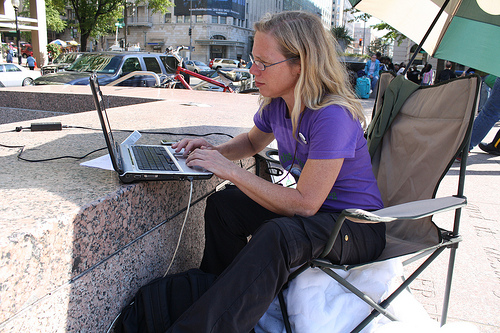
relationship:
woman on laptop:
[250, 21, 374, 267] [88, 73, 185, 194]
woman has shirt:
[250, 21, 374, 267] [278, 104, 382, 217]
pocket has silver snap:
[304, 215, 359, 264] [342, 232, 353, 248]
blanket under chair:
[301, 274, 417, 330] [379, 76, 479, 242]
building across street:
[169, 10, 242, 44] [218, 75, 233, 87]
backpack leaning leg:
[128, 266, 205, 331] [195, 255, 274, 330]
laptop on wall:
[88, 73, 185, 194] [115, 191, 173, 249]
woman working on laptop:
[250, 21, 374, 267] [88, 73, 185, 194]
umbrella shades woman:
[394, 0, 493, 69] [250, 21, 374, 267]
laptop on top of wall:
[88, 73, 185, 194] [115, 191, 173, 249]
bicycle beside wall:
[171, 49, 240, 95] [115, 191, 173, 249]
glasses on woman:
[248, 54, 297, 70] [250, 21, 374, 267]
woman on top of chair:
[250, 21, 374, 267] [379, 76, 479, 242]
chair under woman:
[379, 76, 479, 242] [250, 21, 374, 267]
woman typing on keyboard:
[250, 21, 374, 267] [135, 146, 177, 170]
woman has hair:
[250, 21, 374, 267] [293, 33, 346, 103]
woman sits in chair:
[250, 21, 374, 267] [379, 76, 479, 242]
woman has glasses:
[250, 21, 374, 267] [248, 54, 297, 70]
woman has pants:
[250, 21, 374, 267] [215, 208, 339, 263]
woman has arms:
[250, 21, 374, 267] [274, 120, 351, 200]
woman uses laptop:
[250, 21, 374, 267] [88, 73, 185, 194]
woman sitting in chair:
[250, 21, 374, 267] [379, 76, 479, 242]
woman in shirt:
[250, 21, 374, 267] [278, 104, 382, 217]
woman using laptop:
[250, 21, 374, 267] [88, 73, 185, 194]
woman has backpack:
[250, 21, 374, 267] [128, 266, 205, 331]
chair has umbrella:
[379, 76, 479, 242] [394, 0, 493, 69]